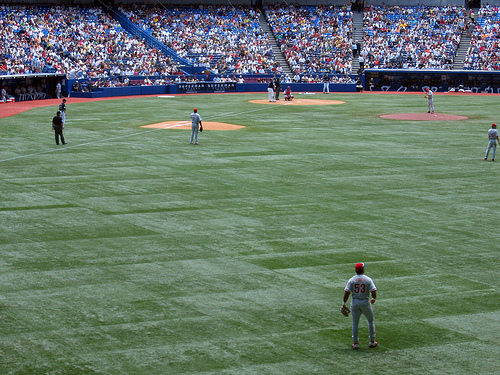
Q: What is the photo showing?
A: It is showing a stadium.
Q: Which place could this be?
A: It is a stadium.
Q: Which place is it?
A: It is a stadium.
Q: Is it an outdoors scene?
A: Yes, it is outdoors.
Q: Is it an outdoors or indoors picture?
A: It is outdoors.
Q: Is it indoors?
A: No, it is outdoors.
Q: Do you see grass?
A: Yes, there is grass.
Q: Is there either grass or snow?
A: Yes, there is grass.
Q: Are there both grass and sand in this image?
A: No, there is grass but no sand.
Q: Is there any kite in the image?
A: No, there are no kites.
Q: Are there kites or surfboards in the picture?
A: No, there are no kites or surfboards.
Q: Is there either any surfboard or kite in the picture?
A: No, there are no kites or surfboards.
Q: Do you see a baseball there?
A: Yes, there is a baseball.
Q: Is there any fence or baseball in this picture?
A: Yes, there is a baseball.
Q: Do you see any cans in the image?
A: No, there are no cans.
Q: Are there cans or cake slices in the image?
A: No, there are no cans or cake slices.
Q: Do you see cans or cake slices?
A: No, there are no cans or cake slices.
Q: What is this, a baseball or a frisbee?
A: This is a baseball.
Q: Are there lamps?
A: No, there are no lamps.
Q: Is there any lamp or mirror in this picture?
A: No, there are no lamps or mirrors.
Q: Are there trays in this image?
A: No, there are no trays.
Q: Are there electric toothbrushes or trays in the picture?
A: No, there are no trays or electric toothbrushes.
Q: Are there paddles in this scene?
A: No, there are no paddles.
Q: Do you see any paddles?
A: No, there are no paddles.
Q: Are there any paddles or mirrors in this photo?
A: No, there are no paddles or mirrors.